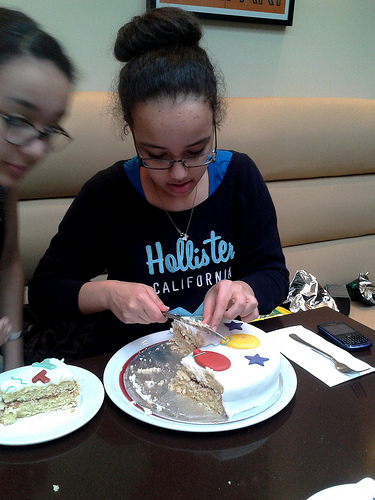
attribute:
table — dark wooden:
[1, 305, 374, 498]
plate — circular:
[96, 316, 311, 440]